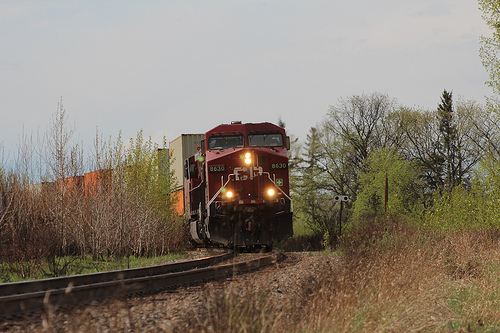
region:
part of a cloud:
[117, 10, 161, 70]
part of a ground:
[255, 251, 280, 289]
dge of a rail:
[162, 262, 192, 294]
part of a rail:
[133, 244, 164, 282]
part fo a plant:
[128, 208, 168, 250]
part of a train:
[233, 126, 280, 184]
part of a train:
[254, 171, 286, 215]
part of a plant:
[370, 248, 410, 314]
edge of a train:
[271, 169, 290, 200]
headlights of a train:
[205, 130, 287, 214]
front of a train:
[195, 119, 292, 244]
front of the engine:
[191, 117, 303, 243]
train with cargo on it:
[27, 105, 298, 260]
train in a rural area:
[0, 99, 471, 269]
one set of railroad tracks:
[11, 229, 310, 325]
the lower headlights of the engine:
[207, 179, 289, 207]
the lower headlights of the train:
[194, 175, 307, 210]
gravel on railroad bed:
[142, 272, 242, 329]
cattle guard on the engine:
[207, 210, 290, 249]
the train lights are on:
[200, 133, 300, 240]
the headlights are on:
[204, 175, 295, 219]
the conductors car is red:
[172, 113, 301, 250]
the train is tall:
[2, 105, 299, 260]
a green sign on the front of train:
[268, 172, 290, 197]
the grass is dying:
[295, 241, 460, 316]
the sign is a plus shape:
[268, 172, 286, 189]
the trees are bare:
[5, 120, 111, 247]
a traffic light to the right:
[312, 177, 354, 246]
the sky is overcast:
[9, 20, 394, 115]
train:
[184, 110, 286, 248]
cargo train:
[184, 123, 317, 261]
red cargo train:
[181, 114, 313, 254]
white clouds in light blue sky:
[5, 4, 111, 59]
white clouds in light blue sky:
[9, 54, 103, 95]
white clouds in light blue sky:
[107, 10, 186, 90]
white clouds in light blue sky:
[204, 15, 279, 61]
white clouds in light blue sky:
[174, 17, 288, 98]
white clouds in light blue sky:
[296, 14, 358, 75]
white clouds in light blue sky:
[348, 16, 453, 74]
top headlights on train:
[239, 150, 254, 170]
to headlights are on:
[239, 148, 254, 165]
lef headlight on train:
[263, 185, 278, 200]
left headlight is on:
[262, 184, 277, 201]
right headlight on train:
[222, 187, 232, 202]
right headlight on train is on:
[223, 190, 235, 199]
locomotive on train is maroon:
[183, 113, 300, 258]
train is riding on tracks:
[6, 110, 300, 255]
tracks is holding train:
[3, 208, 283, 319]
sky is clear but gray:
[1, 1, 498, 196]